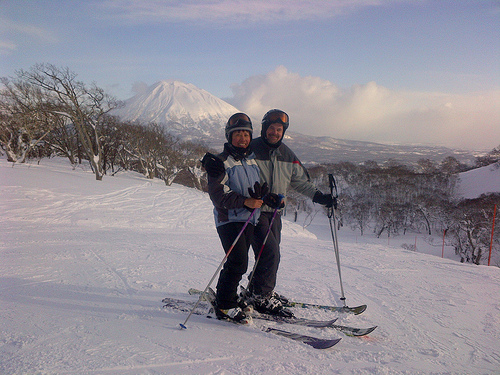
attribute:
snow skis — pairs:
[177, 270, 344, 370]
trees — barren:
[0, 64, 148, 184]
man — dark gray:
[250, 113, 314, 315]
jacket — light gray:
[248, 137, 305, 209]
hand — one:
[312, 189, 337, 210]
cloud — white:
[299, 61, 446, 143]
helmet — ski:
[219, 110, 252, 135]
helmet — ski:
[260, 105, 289, 131]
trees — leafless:
[1, 65, 195, 192]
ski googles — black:
[228, 115, 255, 124]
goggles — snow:
[260, 108, 290, 125]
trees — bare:
[61, 73, 119, 178]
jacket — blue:
[208, 141, 276, 228]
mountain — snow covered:
[111, 71, 243, 143]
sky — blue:
[5, 0, 495, 145]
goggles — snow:
[227, 110, 253, 130]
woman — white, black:
[209, 110, 283, 328]